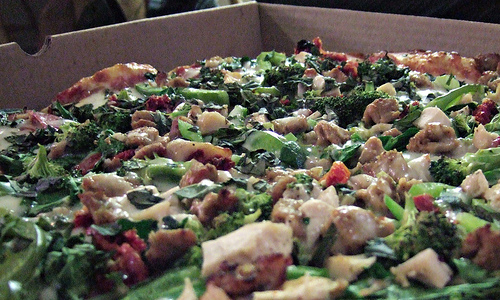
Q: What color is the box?
A: White.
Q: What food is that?
A: Pizza.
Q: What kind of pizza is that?
A: Vegetable.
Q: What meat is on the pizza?
A: Chicken.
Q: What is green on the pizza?
A: Broccoli.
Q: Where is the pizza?
A: In the box.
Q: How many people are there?
A: None.